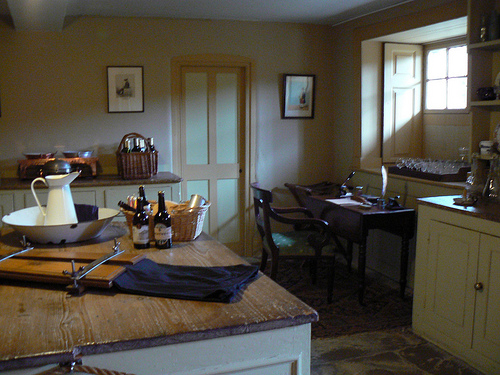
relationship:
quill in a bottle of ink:
[375, 163, 391, 208] [374, 196, 388, 209]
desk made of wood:
[297, 189, 419, 310] [308, 196, 349, 224]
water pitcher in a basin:
[28, 168, 87, 225] [0, 200, 123, 247]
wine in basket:
[136, 183, 153, 214] [114, 194, 214, 244]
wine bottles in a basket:
[114, 182, 151, 210] [114, 194, 214, 244]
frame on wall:
[279, 70, 318, 121] [254, 25, 335, 259]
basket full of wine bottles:
[114, 194, 214, 244] [114, 182, 151, 210]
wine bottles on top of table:
[126, 187, 176, 252] [1, 203, 325, 373]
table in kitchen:
[1, 203, 325, 373] [3, 7, 498, 371]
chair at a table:
[243, 176, 340, 309] [297, 189, 419, 310]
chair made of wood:
[243, 176, 340, 309] [308, 196, 349, 224]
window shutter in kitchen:
[380, 38, 428, 167] [3, 7, 498, 371]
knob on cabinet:
[471, 279, 484, 293] [407, 201, 499, 374]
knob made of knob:
[471, 279, 484, 293] [474, 282, 483, 290]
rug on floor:
[242, 248, 415, 341] [213, 248, 483, 372]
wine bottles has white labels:
[126, 187, 176, 252] [127, 219, 175, 247]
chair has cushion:
[243, 176, 340, 309] [260, 223, 341, 262]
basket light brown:
[114, 194, 214, 244] [180, 220, 192, 231]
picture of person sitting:
[103, 63, 148, 116] [116, 76, 135, 96]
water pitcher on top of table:
[28, 168, 87, 225] [1, 203, 325, 373]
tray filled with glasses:
[385, 163, 471, 182] [394, 156, 475, 176]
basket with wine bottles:
[113, 129, 163, 182] [117, 133, 159, 154]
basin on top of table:
[0, 200, 123, 247] [1, 203, 325, 373]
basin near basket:
[0, 200, 123, 247] [114, 194, 214, 244]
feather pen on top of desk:
[375, 163, 391, 208] [297, 189, 419, 310]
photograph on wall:
[103, 63, 148, 116] [1, 13, 174, 178]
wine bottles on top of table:
[114, 182, 151, 210] [1, 203, 325, 373]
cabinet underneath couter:
[407, 201, 499, 374] [412, 183, 500, 221]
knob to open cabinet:
[471, 279, 484, 293] [407, 201, 499, 374]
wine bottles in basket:
[117, 133, 159, 154] [113, 129, 163, 182]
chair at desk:
[243, 176, 340, 309] [297, 189, 419, 310]